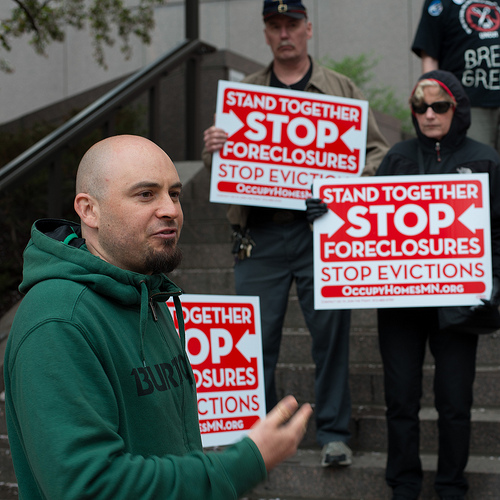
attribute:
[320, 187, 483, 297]
lettering — white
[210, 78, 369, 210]
red sign — protest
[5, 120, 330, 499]
male — bald, white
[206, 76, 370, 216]
sign — white, red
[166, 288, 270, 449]
sign — white, red, large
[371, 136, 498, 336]
jacket — black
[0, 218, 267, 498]
hoodie — green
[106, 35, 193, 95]
stair railing — gray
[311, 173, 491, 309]
sign — white, red, white and red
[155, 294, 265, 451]
sign — white, red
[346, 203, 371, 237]
letter — white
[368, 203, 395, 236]
letter — white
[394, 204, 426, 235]
letter — white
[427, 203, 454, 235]
letter — white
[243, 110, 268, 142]
letter — white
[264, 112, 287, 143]
letter — white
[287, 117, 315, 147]
letter — white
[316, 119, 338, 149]
letter — white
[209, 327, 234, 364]
letter — white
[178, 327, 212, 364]
letter — white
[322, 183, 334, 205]
letter — white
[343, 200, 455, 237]
lettering — white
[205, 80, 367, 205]
sign — white, red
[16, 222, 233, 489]
hoodie — green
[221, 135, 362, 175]
lettering — white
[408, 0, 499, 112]
shirt — black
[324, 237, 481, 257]
lettering — white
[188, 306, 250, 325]
lettering — white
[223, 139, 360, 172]
lettering — white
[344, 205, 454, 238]
lettering — white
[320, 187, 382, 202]
lettering — white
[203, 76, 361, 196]
signs — red, white, three, bright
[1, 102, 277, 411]
man — wearing, green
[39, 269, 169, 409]
sweater — large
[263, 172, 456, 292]
sign — white, red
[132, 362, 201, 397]
letters — black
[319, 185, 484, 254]
lettering — white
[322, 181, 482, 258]
lettering — white